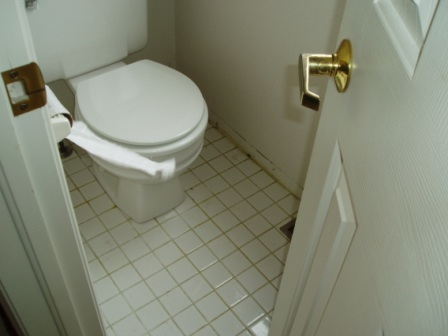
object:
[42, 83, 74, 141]
roll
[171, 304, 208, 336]
tile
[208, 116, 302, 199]
baseboard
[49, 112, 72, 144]
holder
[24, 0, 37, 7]
lever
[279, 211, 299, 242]
heater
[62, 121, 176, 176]
toilet paper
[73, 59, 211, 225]
commode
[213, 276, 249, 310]
tile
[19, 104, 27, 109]
screw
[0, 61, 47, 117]
latch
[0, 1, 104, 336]
frame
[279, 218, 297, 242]
vent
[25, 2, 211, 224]
white toilet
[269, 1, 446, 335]
door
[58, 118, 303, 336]
floor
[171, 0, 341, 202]
wall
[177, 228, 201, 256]
white tile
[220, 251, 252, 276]
white tile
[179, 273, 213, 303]
white tile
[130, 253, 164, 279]
white tile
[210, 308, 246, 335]
white tile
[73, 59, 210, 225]
seat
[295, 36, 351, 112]
door handle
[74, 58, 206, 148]
lid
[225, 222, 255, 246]
tile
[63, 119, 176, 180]
paper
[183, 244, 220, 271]
white tile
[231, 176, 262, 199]
white tile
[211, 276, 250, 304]
white tile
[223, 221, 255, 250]
white tile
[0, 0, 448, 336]
bathroom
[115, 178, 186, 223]
base